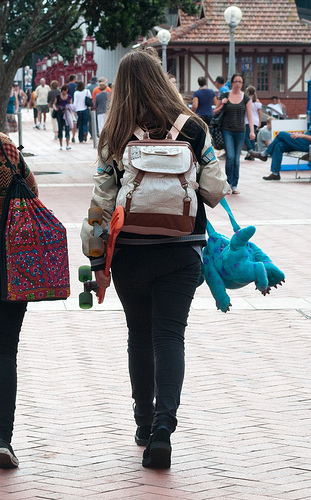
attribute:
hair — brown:
[98, 49, 210, 165]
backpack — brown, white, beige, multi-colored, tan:
[113, 112, 201, 238]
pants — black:
[110, 245, 201, 431]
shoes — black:
[135, 425, 172, 469]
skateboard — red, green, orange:
[78, 204, 125, 309]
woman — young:
[211, 71, 255, 196]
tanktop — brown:
[219, 91, 251, 129]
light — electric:
[223, 4, 243, 25]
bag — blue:
[202, 198, 286, 313]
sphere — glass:
[157, 28, 171, 42]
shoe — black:
[142, 427, 173, 470]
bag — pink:
[4, 200, 69, 300]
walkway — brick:
[2, 106, 311, 498]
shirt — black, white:
[55, 95, 72, 111]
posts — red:
[33, 36, 96, 88]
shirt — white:
[73, 89, 92, 110]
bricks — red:
[194, 315, 301, 464]